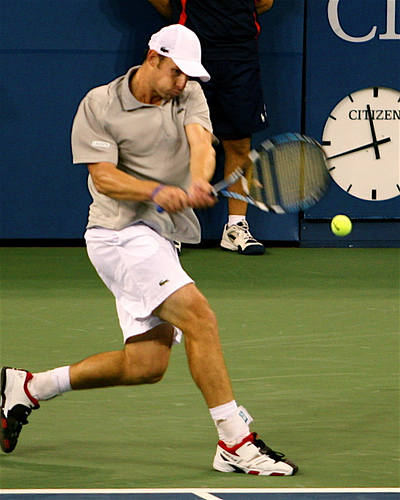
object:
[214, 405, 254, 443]
ankle brace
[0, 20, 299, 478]
man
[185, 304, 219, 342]
knee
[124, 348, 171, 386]
knee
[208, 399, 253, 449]
socks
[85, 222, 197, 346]
shorts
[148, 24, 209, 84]
hat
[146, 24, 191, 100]
player's head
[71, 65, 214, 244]
gray shirt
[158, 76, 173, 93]
cheeks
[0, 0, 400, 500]
photo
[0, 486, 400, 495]
white line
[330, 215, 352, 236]
ball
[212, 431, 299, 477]
shoes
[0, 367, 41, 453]
shoes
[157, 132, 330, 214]
racket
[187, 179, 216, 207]
hand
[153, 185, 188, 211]
hand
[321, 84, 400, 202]
clock